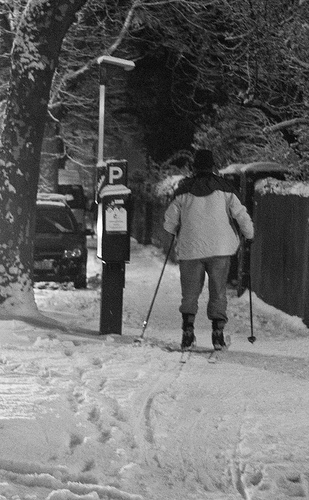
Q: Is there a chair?
A: No, there are no chairs.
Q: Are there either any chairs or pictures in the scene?
A: No, there are no chairs or pictures.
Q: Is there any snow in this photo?
A: Yes, there is snow.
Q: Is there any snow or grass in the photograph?
A: Yes, there is snow.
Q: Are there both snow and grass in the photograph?
A: No, there is snow but no grass.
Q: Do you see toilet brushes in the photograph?
A: No, there are no toilet brushes.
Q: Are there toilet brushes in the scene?
A: No, there are no toilet brushes.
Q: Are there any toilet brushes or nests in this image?
A: No, there are no toilet brushes or nests.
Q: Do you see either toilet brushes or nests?
A: No, there are no toilet brushes or nests.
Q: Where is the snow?
A: The snow is on the ground.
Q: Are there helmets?
A: No, there are no helmets.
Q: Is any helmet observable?
A: No, there are no helmets.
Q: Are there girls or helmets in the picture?
A: No, there are no helmets or girls.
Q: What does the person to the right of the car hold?
A: The man holds the pole.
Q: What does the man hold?
A: The man holds the pole.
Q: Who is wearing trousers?
A: The man is wearing trousers.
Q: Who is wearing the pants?
A: The man is wearing trousers.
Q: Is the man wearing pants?
A: Yes, the man is wearing pants.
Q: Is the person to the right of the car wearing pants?
A: Yes, the man is wearing pants.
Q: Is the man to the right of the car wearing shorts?
A: No, the man is wearing pants.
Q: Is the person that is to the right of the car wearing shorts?
A: No, the man is wearing pants.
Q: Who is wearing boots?
A: The man is wearing boots.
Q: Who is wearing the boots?
A: The man is wearing boots.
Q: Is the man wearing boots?
A: Yes, the man is wearing boots.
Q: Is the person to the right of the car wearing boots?
A: Yes, the man is wearing boots.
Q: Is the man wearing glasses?
A: No, the man is wearing boots.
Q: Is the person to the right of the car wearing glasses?
A: No, the man is wearing boots.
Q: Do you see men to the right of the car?
A: Yes, there is a man to the right of the car.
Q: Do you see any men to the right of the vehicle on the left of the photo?
A: Yes, there is a man to the right of the car.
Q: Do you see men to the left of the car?
A: No, the man is to the right of the car.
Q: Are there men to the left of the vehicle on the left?
A: No, the man is to the right of the car.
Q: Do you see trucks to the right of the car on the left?
A: No, there is a man to the right of the car.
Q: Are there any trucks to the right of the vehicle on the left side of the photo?
A: No, there is a man to the right of the car.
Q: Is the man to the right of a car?
A: Yes, the man is to the right of a car.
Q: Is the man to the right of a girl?
A: No, the man is to the right of a car.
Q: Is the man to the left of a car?
A: No, the man is to the right of a car.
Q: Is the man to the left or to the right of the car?
A: The man is to the right of the car.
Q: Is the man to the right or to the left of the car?
A: The man is to the right of the car.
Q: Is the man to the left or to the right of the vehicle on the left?
A: The man is to the right of the car.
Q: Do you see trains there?
A: No, there are no trains.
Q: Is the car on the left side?
A: Yes, the car is on the left of the image.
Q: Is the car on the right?
A: No, the car is on the left of the image.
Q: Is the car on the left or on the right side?
A: The car is on the left of the image.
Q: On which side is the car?
A: The car is on the left of the image.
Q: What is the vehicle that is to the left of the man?
A: The vehicle is a car.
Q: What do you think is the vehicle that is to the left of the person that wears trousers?
A: The vehicle is a car.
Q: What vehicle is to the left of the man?
A: The vehicle is a car.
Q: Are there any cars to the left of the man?
A: Yes, there is a car to the left of the man.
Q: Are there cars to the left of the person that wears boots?
A: Yes, there is a car to the left of the man.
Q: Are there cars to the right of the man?
A: No, the car is to the left of the man.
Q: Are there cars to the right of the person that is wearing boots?
A: No, the car is to the left of the man.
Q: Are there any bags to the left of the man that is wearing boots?
A: No, there is a car to the left of the man.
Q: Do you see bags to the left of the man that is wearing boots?
A: No, there is a car to the left of the man.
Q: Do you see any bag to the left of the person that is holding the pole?
A: No, there is a car to the left of the man.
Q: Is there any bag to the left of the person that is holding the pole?
A: No, there is a car to the left of the man.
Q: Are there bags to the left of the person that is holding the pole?
A: No, there is a car to the left of the man.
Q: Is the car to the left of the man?
A: Yes, the car is to the left of the man.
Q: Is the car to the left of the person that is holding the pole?
A: Yes, the car is to the left of the man.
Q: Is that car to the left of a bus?
A: No, the car is to the left of the man.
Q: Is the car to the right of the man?
A: No, the car is to the left of the man.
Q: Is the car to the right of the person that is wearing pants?
A: No, the car is to the left of the man.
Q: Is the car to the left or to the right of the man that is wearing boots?
A: The car is to the left of the man.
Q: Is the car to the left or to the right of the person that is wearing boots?
A: The car is to the left of the man.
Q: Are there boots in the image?
A: Yes, there are boots.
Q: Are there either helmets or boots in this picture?
A: Yes, there are boots.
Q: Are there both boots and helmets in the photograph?
A: No, there are boots but no helmets.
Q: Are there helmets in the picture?
A: No, there are no helmets.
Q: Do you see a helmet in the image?
A: No, there are no helmets.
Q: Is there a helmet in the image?
A: No, there are no helmets.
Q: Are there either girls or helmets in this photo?
A: No, there are no helmets or girls.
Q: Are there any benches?
A: No, there are no benches.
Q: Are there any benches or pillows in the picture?
A: No, there are no benches or pillows.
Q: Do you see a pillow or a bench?
A: No, there are no benches or pillows.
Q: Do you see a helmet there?
A: No, there are no helmets.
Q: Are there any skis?
A: Yes, there are skis.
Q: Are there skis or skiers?
A: Yes, there are skis.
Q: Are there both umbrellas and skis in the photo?
A: No, there are skis but no umbrellas.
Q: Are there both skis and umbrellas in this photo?
A: No, there are skis but no umbrellas.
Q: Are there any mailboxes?
A: No, there are no mailboxes.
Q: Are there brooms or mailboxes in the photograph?
A: No, there are no mailboxes or brooms.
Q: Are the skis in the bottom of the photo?
A: Yes, the skis are in the bottom of the image.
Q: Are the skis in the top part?
A: No, the skis are in the bottom of the image.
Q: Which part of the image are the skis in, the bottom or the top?
A: The skis are in the bottom of the image.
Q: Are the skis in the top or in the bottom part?
A: The skis are in the bottom of the image.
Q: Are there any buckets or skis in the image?
A: Yes, there are skis.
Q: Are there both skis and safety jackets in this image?
A: No, there are skis but no safety jackets.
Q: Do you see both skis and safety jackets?
A: No, there are skis but no safety jackets.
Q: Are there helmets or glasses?
A: No, there are no helmets or glasses.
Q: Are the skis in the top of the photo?
A: No, the skis are in the bottom of the image.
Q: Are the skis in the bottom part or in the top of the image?
A: The skis are in the bottom of the image.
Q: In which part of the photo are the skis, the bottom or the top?
A: The skis are in the bottom of the image.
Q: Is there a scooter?
A: No, there are no scooters.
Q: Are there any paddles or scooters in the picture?
A: No, there are no scooters or paddles.